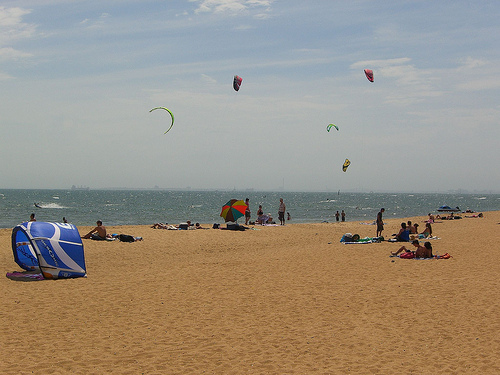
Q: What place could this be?
A: It is a beach.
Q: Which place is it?
A: It is a beach.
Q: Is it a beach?
A: Yes, it is a beach.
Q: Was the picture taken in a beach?
A: Yes, it was taken in a beach.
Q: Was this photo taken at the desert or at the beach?
A: It was taken at the beach.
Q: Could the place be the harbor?
A: No, it is the beach.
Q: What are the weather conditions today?
A: It is cloudy.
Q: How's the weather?
A: It is cloudy.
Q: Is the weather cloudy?
A: Yes, it is cloudy.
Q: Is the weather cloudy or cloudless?
A: It is cloudy.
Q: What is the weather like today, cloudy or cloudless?
A: It is cloudy.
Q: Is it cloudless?
A: No, it is cloudy.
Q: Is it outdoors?
A: Yes, it is outdoors.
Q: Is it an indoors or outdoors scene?
A: It is outdoors.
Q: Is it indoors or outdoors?
A: It is outdoors.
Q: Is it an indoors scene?
A: No, it is outdoors.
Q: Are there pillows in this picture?
A: No, there are no pillows.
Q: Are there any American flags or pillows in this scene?
A: No, there are no pillows or American flags.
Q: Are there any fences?
A: No, there are no fences.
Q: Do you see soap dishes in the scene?
A: No, there are no soap dishes.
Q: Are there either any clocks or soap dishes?
A: No, there are no soap dishes or clocks.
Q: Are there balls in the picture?
A: No, there are no balls.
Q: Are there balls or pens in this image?
A: No, there are no balls or pens.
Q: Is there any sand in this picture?
A: Yes, there is sand.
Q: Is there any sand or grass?
A: Yes, there is sand.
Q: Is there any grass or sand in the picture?
A: Yes, there is sand.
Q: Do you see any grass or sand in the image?
A: Yes, there is sand.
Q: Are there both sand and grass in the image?
A: No, there is sand but no grass.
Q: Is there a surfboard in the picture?
A: No, there are no surfboards.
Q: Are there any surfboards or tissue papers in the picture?
A: No, there are no surfboards or tissue papers.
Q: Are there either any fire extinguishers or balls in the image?
A: No, there are no balls or fire extinguishers.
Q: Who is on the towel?
A: The couple is on the towel.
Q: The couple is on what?
A: The couple is on the towel.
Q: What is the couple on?
A: The couple is on the towel.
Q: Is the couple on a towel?
A: Yes, the couple is on a towel.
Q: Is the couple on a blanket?
A: No, the couple is on a towel.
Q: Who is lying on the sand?
A: The couple is lying on the sand.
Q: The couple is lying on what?
A: The couple is lying on the sand.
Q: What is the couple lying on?
A: The couple is lying on the sand.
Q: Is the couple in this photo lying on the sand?
A: Yes, the couple is lying on the sand.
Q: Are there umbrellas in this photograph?
A: Yes, there is an umbrella.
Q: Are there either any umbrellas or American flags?
A: Yes, there is an umbrella.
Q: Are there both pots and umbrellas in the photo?
A: No, there is an umbrella but no pots.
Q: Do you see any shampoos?
A: No, there are no shampoos.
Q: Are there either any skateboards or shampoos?
A: No, there are no shampoos or skateboards.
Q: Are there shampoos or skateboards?
A: No, there are no shampoos or skateboards.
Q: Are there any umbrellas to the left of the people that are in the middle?
A: Yes, there is an umbrella to the left of the people.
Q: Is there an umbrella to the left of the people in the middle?
A: Yes, there is an umbrella to the left of the people.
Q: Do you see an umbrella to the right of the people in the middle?
A: No, the umbrella is to the left of the people.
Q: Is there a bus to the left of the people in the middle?
A: No, there is an umbrella to the left of the people.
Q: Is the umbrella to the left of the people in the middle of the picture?
A: Yes, the umbrella is to the left of the people.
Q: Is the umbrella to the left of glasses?
A: No, the umbrella is to the left of the people.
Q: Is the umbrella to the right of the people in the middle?
A: No, the umbrella is to the left of the people.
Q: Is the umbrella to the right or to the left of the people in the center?
A: The umbrella is to the left of the people.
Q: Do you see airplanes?
A: No, there are no airplanes.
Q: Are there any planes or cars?
A: No, there are no planes or cars.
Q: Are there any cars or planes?
A: No, there are no planes or cars.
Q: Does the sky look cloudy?
A: Yes, the sky is cloudy.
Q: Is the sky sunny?
A: No, the sky is cloudy.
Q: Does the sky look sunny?
A: No, the sky is cloudy.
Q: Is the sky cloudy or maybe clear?
A: The sky is cloudy.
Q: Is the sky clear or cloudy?
A: The sky is cloudy.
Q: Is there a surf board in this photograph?
A: No, there are no surfboards.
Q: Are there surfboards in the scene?
A: No, there are no surfboards.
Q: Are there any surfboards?
A: No, there are no surfboards.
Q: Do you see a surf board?
A: No, there are no surfboards.